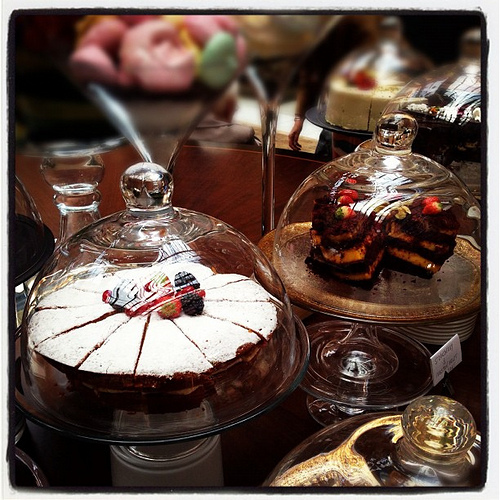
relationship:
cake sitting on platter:
[305, 175, 457, 291] [256, 220, 485, 323]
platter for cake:
[256, 220, 485, 323] [305, 175, 457, 291]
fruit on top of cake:
[103, 270, 205, 318] [28, 266, 279, 414]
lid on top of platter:
[21, 162, 298, 435] [11, 298, 309, 447]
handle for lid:
[120, 160, 173, 222] [21, 162, 298, 435]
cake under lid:
[305, 175, 457, 291] [275, 113, 483, 318]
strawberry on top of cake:
[424, 202, 443, 213] [305, 175, 457, 291]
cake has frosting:
[28, 266, 279, 414] [29, 263, 277, 376]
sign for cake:
[429, 333, 463, 387] [305, 175, 457, 291]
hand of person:
[288, 125, 302, 151] [288, 12, 379, 159]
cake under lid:
[28, 266, 279, 414] [21, 162, 298, 435]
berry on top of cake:
[181, 292, 202, 316] [28, 266, 279, 414]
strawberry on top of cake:
[336, 205, 355, 220] [305, 175, 457, 291]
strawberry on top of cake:
[339, 193, 355, 205] [305, 175, 457, 291]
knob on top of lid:
[373, 115, 418, 157] [275, 113, 483, 318]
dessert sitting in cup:
[65, 16, 248, 92] [75, 83, 235, 172]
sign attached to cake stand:
[429, 333, 463, 387] [253, 271, 484, 410]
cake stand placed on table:
[253, 271, 484, 410] [14, 137, 481, 487]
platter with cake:
[11, 298, 309, 447] [28, 266, 279, 414]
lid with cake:
[21, 162, 298, 435] [28, 266, 279, 414]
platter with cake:
[256, 220, 485, 323] [305, 175, 457, 291]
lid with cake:
[275, 113, 483, 318] [305, 175, 457, 291]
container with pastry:
[317, 17, 436, 132] [327, 75, 411, 131]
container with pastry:
[384, 30, 484, 196] [397, 80, 481, 159]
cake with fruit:
[28, 266, 279, 414] [103, 270, 205, 318]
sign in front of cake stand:
[429, 333, 463, 387] [253, 271, 484, 410]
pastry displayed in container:
[327, 75, 411, 131] [317, 17, 436, 132]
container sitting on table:
[317, 17, 436, 132] [14, 137, 481, 487]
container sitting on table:
[384, 30, 484, 196] [14, 137, 481, 487]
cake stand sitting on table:
[253, 271, 484, 410] [14, 137, 481, 487]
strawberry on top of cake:
[339, 193, 355, 205] [28, 266, 279, 414]